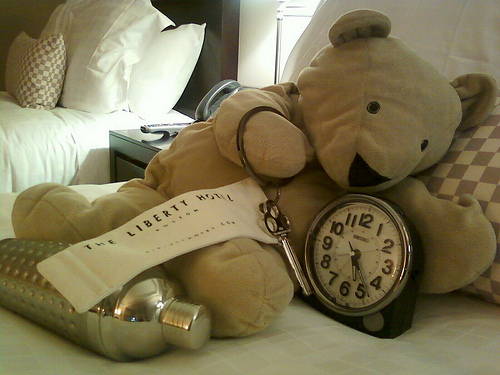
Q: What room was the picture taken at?
A: It was taken at the bedroom.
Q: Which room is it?
A: It is a bedroom.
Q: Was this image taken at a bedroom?
A: Yes, it was taken in a bedroom.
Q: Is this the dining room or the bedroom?
A: It is the bedroom.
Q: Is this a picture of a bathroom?
A: No, the picture is showing a bedroom.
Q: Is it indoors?
A: Yes, it is indoors.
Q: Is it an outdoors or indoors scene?
A: It is indoors.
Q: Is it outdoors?
A: No, it is indoors.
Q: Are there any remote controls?
A: Yes, there is a remote control.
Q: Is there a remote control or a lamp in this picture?
A: Yes, there is a remote control.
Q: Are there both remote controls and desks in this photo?
A: No, there is a remote control but no desks.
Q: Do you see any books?
A: No, there are no books.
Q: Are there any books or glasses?
A: No, there are no books or glasses.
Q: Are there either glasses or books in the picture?
A: No, there are no books or glasses.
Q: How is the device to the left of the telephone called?
A: The device is a remote control.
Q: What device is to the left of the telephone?
A: The device is a remote control.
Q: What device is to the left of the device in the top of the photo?
A: The device is a remote control.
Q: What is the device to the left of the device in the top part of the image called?
A: The device is a remote control.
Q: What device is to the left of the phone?
A: The device is a remote control.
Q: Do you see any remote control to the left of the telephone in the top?
A: Yes, there is a remote control to the left of the telephone.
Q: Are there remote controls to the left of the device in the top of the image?
A: Yes, there is a remote control to the left of the telephone.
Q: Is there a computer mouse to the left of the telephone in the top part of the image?
A: No, there is a remote control to the left of the telephone.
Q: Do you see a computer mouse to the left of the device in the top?
A: No, there is a remote control to the left of the telephone.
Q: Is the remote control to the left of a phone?
A: Yes, the remote control is to the left of a phone.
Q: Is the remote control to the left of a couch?
A: No, the remote control is to the left of a phone.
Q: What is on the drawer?
A: The remote is on the drawer.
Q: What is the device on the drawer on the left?
A: The device is a remote control.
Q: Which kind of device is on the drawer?
A: The device is a remote control.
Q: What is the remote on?
A: The remote is on the drawer.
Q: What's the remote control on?
A: The remote is on the drawer.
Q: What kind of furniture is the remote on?
A: The remote is on the drawer.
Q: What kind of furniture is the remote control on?
A: The remote is on the drawer.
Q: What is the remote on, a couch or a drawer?
A: The remote is on a drawer.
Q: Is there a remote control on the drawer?
A: Yes, there is a remote control on the drawer.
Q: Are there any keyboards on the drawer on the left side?
A: No, there is a remote control on the drawer.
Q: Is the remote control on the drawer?
A: Yes, the remote control is on the drawer.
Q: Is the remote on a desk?
A: No, the remote is on the drawer.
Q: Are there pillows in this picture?
A: Yes, there is a pillow.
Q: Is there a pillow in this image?
A: Yes, there is a pillow.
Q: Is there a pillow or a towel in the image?
A: Yes, there is a pillow.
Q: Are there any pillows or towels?
A: Yes, there is a pillow.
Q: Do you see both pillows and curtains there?
A: No, there is a pillow but no curtains.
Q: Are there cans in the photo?
A: No, there are no cans.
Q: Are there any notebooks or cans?
A: No, there are no cans or notebooks.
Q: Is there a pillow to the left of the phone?
A: Yes, there is a pillow to the left of the phone.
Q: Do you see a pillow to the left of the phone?
A: Yes, there is a pillow to the left of the phone.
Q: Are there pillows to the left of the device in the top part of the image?
A: Yes, there is a pillow to the left of the phone.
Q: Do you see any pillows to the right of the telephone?
A: No, the pillow is to the left of the telephone.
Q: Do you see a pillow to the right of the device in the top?
A: No, the pillow is to the left of the telephone.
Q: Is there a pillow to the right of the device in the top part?
A: No, the pillow is to the left of the telephone.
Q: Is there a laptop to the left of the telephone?
A: No, there is a pillow to the left of the telephone.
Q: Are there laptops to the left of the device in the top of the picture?
A: No, there is a pillow to the left of the telephone.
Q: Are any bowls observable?
A: No, there are no bowls.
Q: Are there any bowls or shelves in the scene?
A: No, there are no bowls or shelves.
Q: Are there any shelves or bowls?
A: No, there are no bowls or shelves.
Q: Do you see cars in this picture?
A: No, there are no cars.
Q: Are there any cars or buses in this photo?
A: No, there are no cars or buses.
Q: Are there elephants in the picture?
A: No, there are no elephants.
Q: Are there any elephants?
A: No, there are no elephants.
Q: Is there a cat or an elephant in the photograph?
A: No, there are no elephants or cats.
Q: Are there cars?
A: No, there are no cars.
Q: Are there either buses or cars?
A: No, there are no cars or buses.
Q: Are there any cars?
A: No, there are no cars.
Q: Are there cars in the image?
A: No, there are no cars.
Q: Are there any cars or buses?
A: No, there are no cars or buses.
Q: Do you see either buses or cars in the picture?
A: No, there are no cars or buses.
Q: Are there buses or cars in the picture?
A: No, there are no cars or buses.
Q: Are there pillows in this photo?
A: Yes, there is a pillow.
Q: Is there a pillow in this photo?
A: Yes, there is a pillow.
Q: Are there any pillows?
A: Yes, there is a pillow.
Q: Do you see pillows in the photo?
A: Yes, there is a pillow.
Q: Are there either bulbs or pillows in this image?
A: Yes, there is a pillow.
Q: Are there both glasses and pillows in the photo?
A: No, there is a pillow but no glasses.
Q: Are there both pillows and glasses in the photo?
A: No, there is a pillow but no glasses.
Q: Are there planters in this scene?
A: No, there are no planters.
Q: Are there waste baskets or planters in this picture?
A: No, there are no planters or waste baskets.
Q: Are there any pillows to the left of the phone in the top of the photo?
A: Yes, there is a pillow to the left of the telephone.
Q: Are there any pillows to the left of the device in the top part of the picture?
A: Yes, there is a pillow to the left of the telephone.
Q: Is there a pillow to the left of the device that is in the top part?
A: Yes, there is a pillow to the left of the telephone.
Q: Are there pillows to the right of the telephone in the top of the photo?
A: No, the pillow is to the left of the telephone.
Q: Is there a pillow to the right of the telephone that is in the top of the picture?
A: No, the pillow is to the left of the telephone.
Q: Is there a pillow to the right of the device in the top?
A: No, the pillow is to the left of the telephone.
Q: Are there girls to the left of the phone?
A: No, there is a pillow to the left of the phone.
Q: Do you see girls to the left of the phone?
A: No, there is a pillow to the left of the phone.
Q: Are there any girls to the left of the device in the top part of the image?
A: No, there is a pillow to the left of the phone.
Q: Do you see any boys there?
A: No, there are no boys.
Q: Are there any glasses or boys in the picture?
A: No, there are no boys or glasses.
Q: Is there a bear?
A: Yes, there is a bear.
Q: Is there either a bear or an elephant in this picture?
A: Yes, there is a bear.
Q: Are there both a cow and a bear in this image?
A: No, there is a bear but no cows.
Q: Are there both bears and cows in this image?
A: No, there is a bear but no cows.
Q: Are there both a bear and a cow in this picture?
A: No, there is a bear but no cows.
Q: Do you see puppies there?
A: No, there are no puppies.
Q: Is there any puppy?
A: No, there are no puppies.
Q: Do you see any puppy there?
A: No, there are no puppies.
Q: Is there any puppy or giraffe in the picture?
A: No, there are no puppies or giraffes.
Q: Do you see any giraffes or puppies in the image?
A: No, there are no puppies or giraffes.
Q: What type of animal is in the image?
A: The animal is a bear.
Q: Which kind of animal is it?
A: The animal is a bear.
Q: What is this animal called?
A: This is a bear.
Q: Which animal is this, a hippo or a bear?
A: This is a bear.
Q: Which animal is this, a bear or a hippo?
A: This is a bear.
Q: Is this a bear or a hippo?
A: This is a bear.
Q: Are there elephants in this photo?
A: No, there are no elephants.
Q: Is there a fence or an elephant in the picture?
A: No, there are no elephants or fences.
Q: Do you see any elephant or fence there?
A: No, there are no elephants or fences.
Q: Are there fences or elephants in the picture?
A: No, there are no elephants or fences.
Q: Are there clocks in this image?
A: Yes, there is a clock.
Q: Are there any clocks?
A: Yes, there is a clock.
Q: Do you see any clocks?
A: Yes, there is a clock.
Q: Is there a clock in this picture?
A: Yes, there is a clock.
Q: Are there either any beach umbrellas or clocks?
A: Yes, there is a clock.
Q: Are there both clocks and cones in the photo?
A: No, there is a clock but no cones.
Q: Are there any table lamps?
A: No, there are no table lamps.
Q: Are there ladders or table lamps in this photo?
A: No, there are no table lamps or ladders.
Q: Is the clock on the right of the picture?
A: Yes, the clock is on the right of the image.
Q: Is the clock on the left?
A: No, the clock is on the right of the image.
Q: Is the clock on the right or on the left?
A: The clock is on the right of the image.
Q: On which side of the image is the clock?
A: The clock is on the right of the image.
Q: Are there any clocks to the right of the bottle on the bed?
A: Yes, there is a clock to the right of the bottle.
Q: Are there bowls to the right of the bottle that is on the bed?
A: No, there is a clock to the right of the bottle.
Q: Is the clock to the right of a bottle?
A: Yes, the clock is to the right of a bottle.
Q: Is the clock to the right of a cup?
A: No, the clock is to the right of a bottle.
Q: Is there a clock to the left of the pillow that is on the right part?
A: Yes, there is a clock to the left of the pillow.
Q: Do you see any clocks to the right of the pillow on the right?
A: No, the clock is to the left of the pillow.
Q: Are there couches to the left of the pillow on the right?
A: No, there is a clock to the left of the pillow.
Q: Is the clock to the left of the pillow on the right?
A: Yes, the clock is to the left of the pillow.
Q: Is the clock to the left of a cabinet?
A: No, the clock is to the left of the pillow.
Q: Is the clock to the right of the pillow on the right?
A: No, the clock is to the left of the pillow.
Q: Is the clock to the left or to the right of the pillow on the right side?
A: The clock is to the left of the pillow.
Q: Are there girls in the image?
A: No, there are no girls.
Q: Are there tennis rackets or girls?
A: No, there are no girls or tennis rackets.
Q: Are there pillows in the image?
A: Yes, there is a pillow.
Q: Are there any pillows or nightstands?
A: Yes, there is a pillow.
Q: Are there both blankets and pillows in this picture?
A: No, there is a pillow but no blankets.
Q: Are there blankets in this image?
A: No, there are no blankets.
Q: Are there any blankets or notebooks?
A: No, there are no blankets or notebooks.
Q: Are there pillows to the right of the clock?
A: Yes, there is a pillow to the right of the clock.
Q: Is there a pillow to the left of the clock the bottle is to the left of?
A: No, the pillow is to the right of the clock.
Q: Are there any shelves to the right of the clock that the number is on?
A: No, there is a pillow to the right of the clock.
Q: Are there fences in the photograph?
A: No, there are no fences.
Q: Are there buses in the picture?
A: No, there are no buses.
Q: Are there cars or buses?
A: No, there are no buses or cars.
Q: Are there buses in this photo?
A: No, there are no buses.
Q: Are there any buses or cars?
A: No, there are no buses or cars.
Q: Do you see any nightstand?
A: Yes, there is a nightstand.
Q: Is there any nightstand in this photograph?
A: Yes, there is a nightstand.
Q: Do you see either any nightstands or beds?
A: Yes, there is a nightstand.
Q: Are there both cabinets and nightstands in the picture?
A: No, there is a nightstand but no cabinets.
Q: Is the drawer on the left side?
A: Yes, the drawer is on the left of the image.